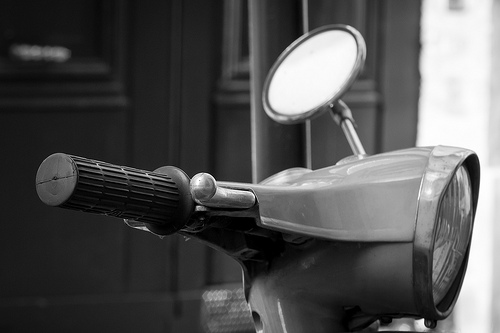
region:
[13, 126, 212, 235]
Black grip on handlebar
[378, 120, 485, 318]
Round light on front of scooter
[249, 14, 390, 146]
The mirror is silver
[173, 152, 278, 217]
Shiny silver brake lever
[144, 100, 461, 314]
The scooter is light colored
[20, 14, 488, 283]
A dark colored building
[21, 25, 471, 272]
Scooter is in front of the building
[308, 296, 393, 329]
Black wire on scooter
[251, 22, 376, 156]
Round mirror attached to scooter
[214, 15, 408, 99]
The building has a window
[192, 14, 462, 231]
a small rearview mirror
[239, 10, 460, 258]
a small side mirror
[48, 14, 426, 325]
a mirror on a bike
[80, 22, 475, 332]
a mirror on a moped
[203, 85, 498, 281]
a headlight on a bike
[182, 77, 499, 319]
a headlight on a moped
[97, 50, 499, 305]
a headlight on an electric bike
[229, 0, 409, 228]
a small mirror on an electric bike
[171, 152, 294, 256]
a bike's break handle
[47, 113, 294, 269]
an electric bike's handle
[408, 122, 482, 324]
the light is off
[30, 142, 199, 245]
the grip is black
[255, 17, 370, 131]
the mirror is round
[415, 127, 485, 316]
the light is round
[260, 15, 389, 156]
the mirror is at an angle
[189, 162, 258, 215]
the brake is metal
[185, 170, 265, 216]
the brake is silver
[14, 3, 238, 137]
the door is big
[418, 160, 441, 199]
around the light is chrome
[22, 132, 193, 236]
the grip is rubber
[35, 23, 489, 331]
close-up of front of motorcycle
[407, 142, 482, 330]
motorcycle headlight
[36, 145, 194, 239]
black rubber motorcycle handle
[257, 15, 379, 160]
round mirror on left side of motorcycle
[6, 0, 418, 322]
double door behind motorcycle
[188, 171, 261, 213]
silver handbrake on motorcycle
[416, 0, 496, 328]
blurry white brick next to door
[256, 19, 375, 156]
mirror with silver edges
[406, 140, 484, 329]
headlight with silver edges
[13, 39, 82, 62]
light entering through door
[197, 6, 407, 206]
a small circle mirror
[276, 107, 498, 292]
a single head light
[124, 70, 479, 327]
a single head light on front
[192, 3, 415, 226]
a mirror on a bike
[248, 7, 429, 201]
a mirror on a moped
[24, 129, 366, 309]
a handle bar on a bike